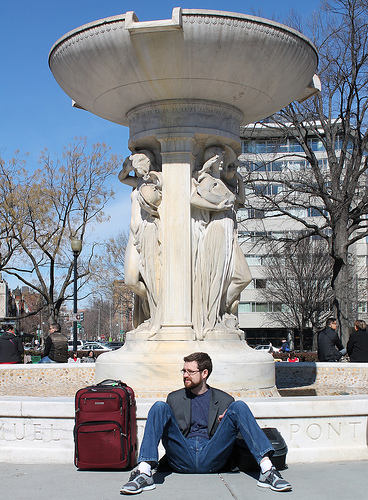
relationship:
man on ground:
[149, 364, 252, 465] [34, 464, 69, 499]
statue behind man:
[86, 40, 273, 326] [149, 364, 252, 465]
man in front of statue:
[149, 364, 252, 465] [86, 40, 273, 326]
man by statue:
[149, 364, 252, 465] [86, 40, 273, 326]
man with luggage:
[149, 364, 252, 465] [76, 374, 133, 462]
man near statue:
[149, 364, 252, 465] [86, 40, 273, 326]